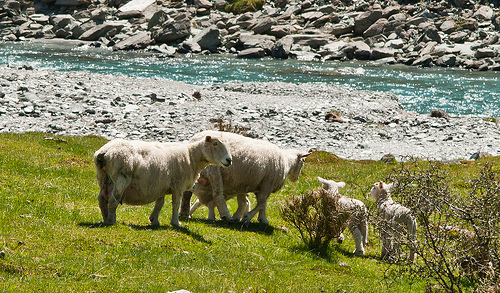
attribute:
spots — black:
[118, 173, 132, 183]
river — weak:
[0, 34, 498, 125]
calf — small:
[308, 164, 433, 265]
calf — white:
[310, 170, 373, 260]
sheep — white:
[88, 123, 318, 243]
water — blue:
[150, 48, 290, 80]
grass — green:
[12, 181, 92, 271]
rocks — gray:
[15, 79, 204, 122]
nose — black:
[222, 154, 232, 164]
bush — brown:
[273, 181, 331, 251]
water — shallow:
[75, 54, 462, 92]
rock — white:
[4, 81, 100, 124]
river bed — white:
[1, 75, 170, 133]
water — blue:
[166, 57, 298, 82]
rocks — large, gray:
[272, 8, 404, 62]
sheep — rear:
[86, 126, 240, 233]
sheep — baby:
[359, 175, 426, 269]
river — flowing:
[4, 46, 498, 95]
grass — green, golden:
[12, 134, 93, 234]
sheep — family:
[82, 119, 427, 273]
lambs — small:
[304, 168, 427, 273]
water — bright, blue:
[4, 41, 498, 104]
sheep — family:
[87, 126, 451, 288]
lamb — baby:
[117, 131, 219, 217]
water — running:
[155, 32, 452, 92]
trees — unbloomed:
[376, 160, 496, 289]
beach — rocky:
[82, 68, 317, 131]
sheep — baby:
[288, 178, 465, 256]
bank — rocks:
[119, 11, 462, 108]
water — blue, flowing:
[131, 43, 451, 116]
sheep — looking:
[119, 123, 285, 190]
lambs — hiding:
[184, 169, 249, 229]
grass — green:
[14, 160, 171, 274]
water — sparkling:
[223, 40, 440, 94]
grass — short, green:
[103, 208, 272, 286]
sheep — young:
[306, 182, 446, 264]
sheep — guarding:
[85, 129, 389, 267]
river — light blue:
[152, 46, 459, 108]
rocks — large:
[206, 21, 453, 46]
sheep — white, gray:
[109, 134, 331, 237]